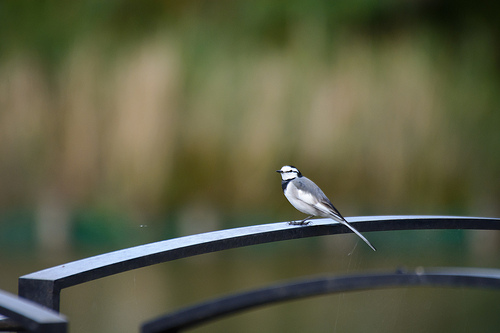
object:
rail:
[17, 214, 498, 313]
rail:
[0, 289, 70, 332]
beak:
[276, 170, 283, 172]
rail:
[137, 266, 499, 333]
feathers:
[295, 184, 320, 208]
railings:
[17, 215, 500, 333]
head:
[280, 165, 302, 181]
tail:
[329, 207, 378, 251]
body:
[282, 176, 330, 215]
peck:
[276, 170, 282, 173]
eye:
[290, 170, 293, 172]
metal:
[0, 214, 499, 331]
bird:
[276, 165, 378, 252]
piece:
[0, 199, 499, 333]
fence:
[137, 268, 499, 331]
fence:
[17, 215, 500, 312]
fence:
[0, 290, 69, 333]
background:
[95, 67, 211, 145]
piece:
[276, 165, 344, 225]